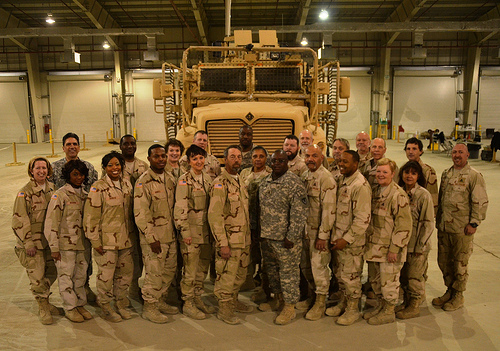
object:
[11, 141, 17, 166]
pole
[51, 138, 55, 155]
pole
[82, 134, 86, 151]
pole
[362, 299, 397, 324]
boots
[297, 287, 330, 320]
boots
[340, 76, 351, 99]
mirror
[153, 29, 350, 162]
truck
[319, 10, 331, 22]
light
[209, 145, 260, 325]
man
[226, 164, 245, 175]
beard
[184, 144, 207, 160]
hair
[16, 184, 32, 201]
shoulders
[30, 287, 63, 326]
boots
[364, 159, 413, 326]
person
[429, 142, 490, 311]
person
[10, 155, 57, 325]
person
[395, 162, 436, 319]
person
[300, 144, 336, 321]
person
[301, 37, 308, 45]
light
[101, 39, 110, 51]
light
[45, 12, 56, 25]
light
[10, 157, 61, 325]
woman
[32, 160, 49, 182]
face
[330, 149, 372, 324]
man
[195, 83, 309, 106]
wipes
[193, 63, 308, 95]
windshield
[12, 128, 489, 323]
military personnel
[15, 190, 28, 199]
patches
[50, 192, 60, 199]
patches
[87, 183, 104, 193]
patches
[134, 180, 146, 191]
patches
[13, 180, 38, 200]
shoulders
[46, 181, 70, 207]
shoulders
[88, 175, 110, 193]
shoulders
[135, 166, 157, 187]
shoulders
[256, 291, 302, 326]
boots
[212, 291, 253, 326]
boots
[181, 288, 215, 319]
boots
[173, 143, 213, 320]
soldier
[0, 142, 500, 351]
ground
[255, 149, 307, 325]
man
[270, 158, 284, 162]
glasses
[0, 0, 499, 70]
ceiling